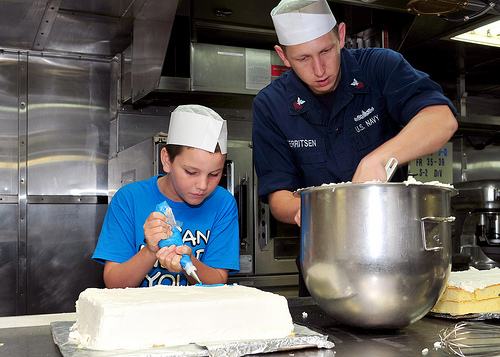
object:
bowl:
[294, 180, 460, 330]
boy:
[91, 105, 240, 289]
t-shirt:
[93, 174, 240, 288]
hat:
[166, 104, 228, 154]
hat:
[271, 0, 337, 48]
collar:
[284, 68, 372, 117]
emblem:
[294, 97, 304, 108]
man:
[252, 0, 460, 301]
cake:
[71, 285, 297, 346]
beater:
[437, 319, 499, 355]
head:
[273, 0, 346, 93]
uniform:
[254, 45, 455, 203]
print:
[354, 107, 386, 133]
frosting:
[84, 283, 282, 314]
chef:
[254, 0, 463, 300]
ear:
[158, 145, 171, 176]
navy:
[365, 112, 384, 128]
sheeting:
[27, 54, 109, 194]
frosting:
[194, 283, 225, 289]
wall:
[2, 53, 113, 317]